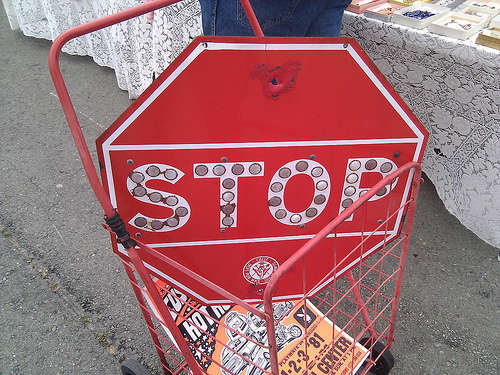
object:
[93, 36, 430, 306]
sign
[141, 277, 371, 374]
poster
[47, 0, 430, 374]
cart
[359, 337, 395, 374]
wheel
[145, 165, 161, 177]
spot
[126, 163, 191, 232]
letter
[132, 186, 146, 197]
spot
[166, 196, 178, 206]
spot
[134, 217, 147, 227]
spot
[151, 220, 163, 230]
spot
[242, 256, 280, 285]
logo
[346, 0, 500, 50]
jewelry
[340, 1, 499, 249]
table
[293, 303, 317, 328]
playboy bunny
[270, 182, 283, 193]
spot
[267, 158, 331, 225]
letter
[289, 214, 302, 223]
spot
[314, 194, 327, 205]
spot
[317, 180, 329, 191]
spot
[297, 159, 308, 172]
spot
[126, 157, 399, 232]
stop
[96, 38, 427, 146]
top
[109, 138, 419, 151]
line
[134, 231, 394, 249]
line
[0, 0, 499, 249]
tablecloth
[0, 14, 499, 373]
ground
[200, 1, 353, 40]
person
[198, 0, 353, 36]
jeans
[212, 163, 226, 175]
spot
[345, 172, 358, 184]
spot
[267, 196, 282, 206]
spot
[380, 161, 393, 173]
spot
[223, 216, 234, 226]
spot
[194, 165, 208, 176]
spot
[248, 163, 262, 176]
spot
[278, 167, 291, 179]
spot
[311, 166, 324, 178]
spot